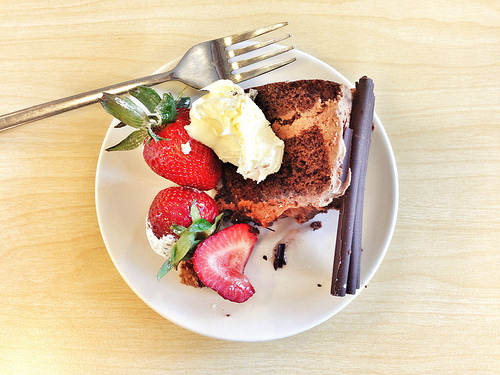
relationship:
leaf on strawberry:
[129, 83, 176, 118] [141, 114, 222, 191]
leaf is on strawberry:
[98, 85, 189, 151] [97, 85, 221, 189]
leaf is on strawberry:
[160, 92, 177, 122] [142, 108, 220, 191]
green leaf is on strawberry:
[170, 216, 214, 256] [200, 224, 261, 305]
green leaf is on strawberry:
[181, 205, 203, 239] [129, 127, 214, 185]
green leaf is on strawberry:
[90, 85, 195, 139] [139, 186, 241, 242]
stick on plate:
[330, 75, 379, 302] [85, 33, 401, 347]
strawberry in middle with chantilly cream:
[145, 187, 225, 279] [145, 216, 178, 258]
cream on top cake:
[177, 76, 289, 191] [217, 74, 354, 230]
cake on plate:
[204, 66, 365, 236] [88, 37, 432, 369]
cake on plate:
[204, 75, 356, 232] [85, 33, 401, 347]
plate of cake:
[85, 33, 401, 347] [204, 75, 356, 232]